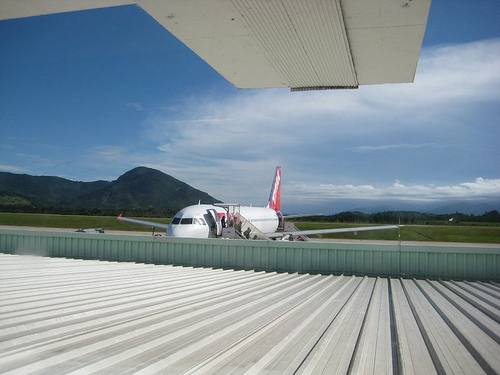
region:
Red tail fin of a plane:
[268, 163, 285, 213]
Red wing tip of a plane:
[112, 212, 124, 221]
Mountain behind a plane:
[112, 157, 224, 219]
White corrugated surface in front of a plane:
[25, 259, 360, 359]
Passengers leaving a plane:
[221, 208, 271, 245]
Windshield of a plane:
[167, 214, 196, 227]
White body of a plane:
[197, 204, 275, 239]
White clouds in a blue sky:
[307, 179, 493, 201]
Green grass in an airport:
[384, 223, 493, 240]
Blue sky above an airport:
[17, 114, 119, 149]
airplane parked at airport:
[119, 161, 396, 248]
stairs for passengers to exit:
[218, 210, 273, 248]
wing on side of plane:
[301, 215, 402, 245]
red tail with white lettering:
[264, 164, 286, 214]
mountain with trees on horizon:
[67, 160, 182, 209]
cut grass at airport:
[422, 225, 482, 239]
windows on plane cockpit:
[168, 212, 205, 230]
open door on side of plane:
[203, 207, 226, 237]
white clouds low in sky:
[401, 176, 470, 203]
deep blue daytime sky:
[52, 20, 125, 91]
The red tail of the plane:
[268, 164, 283, 214]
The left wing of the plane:
[113, 211, 169, 231]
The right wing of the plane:
[255, 221, 404, 236]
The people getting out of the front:
[221, 212, 272, 247]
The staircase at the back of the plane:
[278, 214, 309, 240]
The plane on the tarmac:
[115, 165, 405, 241]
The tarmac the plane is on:
[2, 222, 499, 249]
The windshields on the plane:
[171, 213, 206, 226]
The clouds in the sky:
[76, 40, 498, 216]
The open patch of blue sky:
[0, 0, 135, 139]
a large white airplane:
[115, 164, 401, 242]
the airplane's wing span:
[117, 214, 399, 236]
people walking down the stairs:
[221, 212, 271, 239]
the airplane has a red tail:
[265, 165, 283, 210]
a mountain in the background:
[48, 166, 246, 213]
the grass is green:
[1, 210, 499, 241]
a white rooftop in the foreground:
[1, 228, 499, 373]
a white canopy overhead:
[1, 0, 431, 90]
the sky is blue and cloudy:
[1, 0, 498, 216]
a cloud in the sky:
[78, 37, 499, 164]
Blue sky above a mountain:
[7, 48, 135, 179]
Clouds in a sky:
[191, 102, 471, 185]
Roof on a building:
[85, 236, 325, 372]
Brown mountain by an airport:
[15, 164, 181, 206]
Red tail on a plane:
[259, 163, 306, 217]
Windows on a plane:
[160, 211, 214, 228]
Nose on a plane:
[145, 218, 213, 246]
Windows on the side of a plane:
[226, 206, 297, 231]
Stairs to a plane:
[209, 208, 287, 258]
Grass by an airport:
[315, 215, 462, 242]